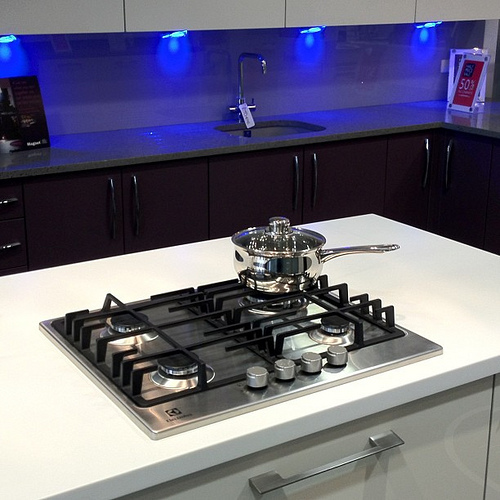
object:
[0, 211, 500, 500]
kitchen island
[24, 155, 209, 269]
cabinets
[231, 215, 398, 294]
pan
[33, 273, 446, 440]
stove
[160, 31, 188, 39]
light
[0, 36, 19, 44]
light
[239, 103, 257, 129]
pricetag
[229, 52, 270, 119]
faucet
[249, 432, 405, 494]
handle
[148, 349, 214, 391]
burner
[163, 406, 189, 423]
mark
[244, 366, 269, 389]
knob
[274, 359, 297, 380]
knob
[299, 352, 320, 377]
knob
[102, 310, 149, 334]
burner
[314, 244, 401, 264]
handle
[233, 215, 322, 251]
lid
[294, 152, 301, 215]
handle